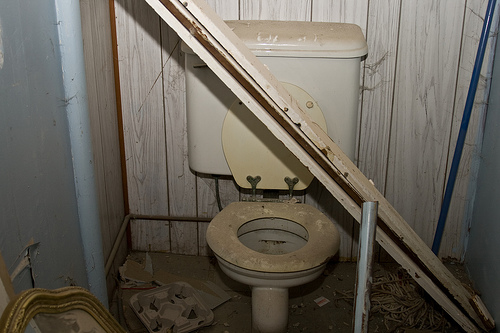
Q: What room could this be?
A: It is a bathroom.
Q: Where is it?
A: This is at the bathroom.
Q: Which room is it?
A: It is a bathroom.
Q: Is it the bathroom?
A: Yes, it is the bathroom.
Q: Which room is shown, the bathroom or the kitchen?
A: It is the bathroom.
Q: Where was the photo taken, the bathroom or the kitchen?
A: It was taken at the bathroom.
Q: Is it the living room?
A: No, it is the bathroom.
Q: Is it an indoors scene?
A: Yes, it is indoors.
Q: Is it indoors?
A: Yes, it is indoors.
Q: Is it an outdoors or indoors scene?
A: It is indoors.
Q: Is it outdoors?
A: No, it is indoors.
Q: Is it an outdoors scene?
A: No, it is indoors.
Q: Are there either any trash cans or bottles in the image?
A: No, there are no trash cans or bottles.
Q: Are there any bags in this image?
A: No, there are no bags.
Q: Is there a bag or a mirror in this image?
A: No, there are no bags or mirrors.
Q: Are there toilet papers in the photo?
A: No, there are no toilet papers.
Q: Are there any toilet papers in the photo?
A: No, there are no toilet papers.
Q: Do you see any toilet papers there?
A: No, there are no toilet papers.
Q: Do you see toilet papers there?
A: No, there are no toilet papers.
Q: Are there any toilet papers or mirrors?
A: No, there are no toilet papers or mirrors.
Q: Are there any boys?
A: No, there are no boys.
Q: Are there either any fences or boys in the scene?
A: No, there are no boys or fences.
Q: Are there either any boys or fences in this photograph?
A: No, there are no boys or fences.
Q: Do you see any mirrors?
A: No, there are no mirrors.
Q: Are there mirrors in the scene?
A: No, there are no mirrors.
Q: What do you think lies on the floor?
A: The picture frame lies on the floor.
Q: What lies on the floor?
A: The picture frame lies on the floor.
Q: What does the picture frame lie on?
A: The picture frame lies on the floor.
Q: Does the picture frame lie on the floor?
A: Yes, the picture frame lies on the floor.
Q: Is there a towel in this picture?
A: No, there are no towels.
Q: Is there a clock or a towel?
A: No, there are no towels or clocks.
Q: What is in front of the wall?
A: The toilet is in front of the wall.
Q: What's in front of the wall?
A: The toilet is in front of the wall.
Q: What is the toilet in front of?
A: The toilet is in front of the wall.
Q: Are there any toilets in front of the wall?
A: Yes, there is a toilet in front of the wall.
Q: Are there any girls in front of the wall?
A: No, there is a toilet in front of the wall.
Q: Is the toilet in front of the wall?
A: Yes, the toilet is in front of the wall.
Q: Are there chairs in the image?
A: No, there are no chairs.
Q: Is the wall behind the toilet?
A: Yes, the wall is behind the toilet.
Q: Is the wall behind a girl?
A: No, the wall is behind the toilet.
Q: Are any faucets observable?
A: No, there are no faucets.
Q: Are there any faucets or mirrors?
A: No, there are no faucets or mirrors.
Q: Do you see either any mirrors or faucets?
A: No, there are no faucets or mirrors.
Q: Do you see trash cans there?
A: No, there are no trash cans.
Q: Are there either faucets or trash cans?
A: No, there are no trash cans or faucets.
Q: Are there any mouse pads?
A: No, there are no mouse pads.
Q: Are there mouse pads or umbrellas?
A: No, there are no mouse pads or umbrellas.